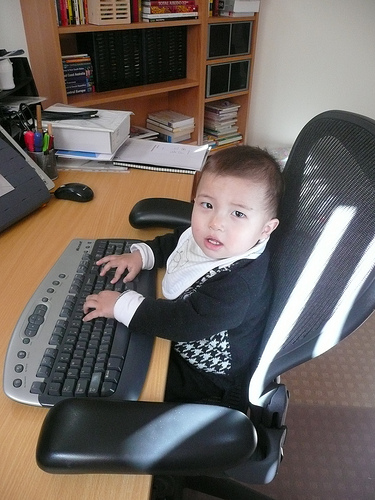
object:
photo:
[4, 5, 375, 500]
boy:
[79, 144, 283, 405]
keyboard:
[2, 235, 159, 411]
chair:
[40, 109, 375, 499]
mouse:
[52, 182, 95, 202]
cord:
[49, 189, 55, 197]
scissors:
[10, 103, 37, 135]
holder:
[20, 150, 58, 180]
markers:
[33, 129, 45, 151]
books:
[61, 52, 89, 63]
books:
[144, 108, 195, 129]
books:
[203, 102, 242, 111]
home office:
[2, 5, 374, 499]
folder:
[108, 135, 212, 178]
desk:
[4, 115, 199, 499]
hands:
[77, 283, 120, 322]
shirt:
[111, 227, 270, 390]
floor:
[151, 308, 374, 498]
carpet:
[149, 313, 374, 497]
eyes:
[229, 208, 251, 225]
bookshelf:
[16, 2, 205, 151]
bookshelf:
[204, 3, 260, 152]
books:
[65, 86, 94, 97]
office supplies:
[42, 133, 50, 154]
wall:
[246, 5, 374, 158]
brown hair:
[199, 145, 285, 218]